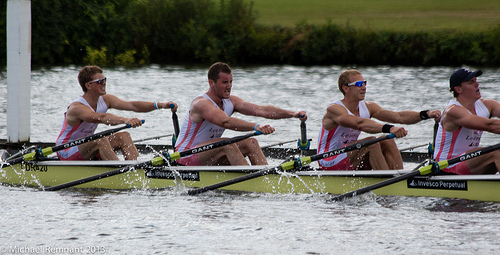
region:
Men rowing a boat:
[3, 61, 499, 198]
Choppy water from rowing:
[1, 165, 499, 243]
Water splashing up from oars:
[1, 160, 368, 197]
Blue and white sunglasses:
[346, 79, 369, 88]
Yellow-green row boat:
[3, 141, 499, 201]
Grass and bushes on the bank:
[32, 0, 499, 60]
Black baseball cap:
[451, 68, 483, 87]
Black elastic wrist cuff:
[418, 108, 431, 122]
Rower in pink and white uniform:
[56, 66, 177, 158]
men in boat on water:
[28, 51, 495, 208]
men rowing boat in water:
[31, 46, 475, 215]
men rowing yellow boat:
[25, 67, 499, 224]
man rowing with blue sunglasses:
[314, 53, 416, 190]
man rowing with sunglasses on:
[45, 44, 142, 171]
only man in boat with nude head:
[170, 55, 282, 195]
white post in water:
[3, 5, 49, 145]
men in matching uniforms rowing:
[21, 55, 496, 209]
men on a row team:
[37, 36, 496, 178]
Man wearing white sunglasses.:
[70, 62, 115, 94]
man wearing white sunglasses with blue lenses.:
[335, 63, 372, 111]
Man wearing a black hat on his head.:
[444, 57, 489, 104]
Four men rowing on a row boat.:
[5, 36, 497, 208]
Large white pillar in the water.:
[3, 2, 35, 146]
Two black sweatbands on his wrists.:
[375, 103, 445, 134]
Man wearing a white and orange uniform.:
[173, 57, 288, 167]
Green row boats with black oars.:
[7, 125, 498, 214]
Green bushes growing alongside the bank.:
[33, 4, 264, 66]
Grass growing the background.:
[260, 2, 496, 34]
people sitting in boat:
[65, 40, 492, 235]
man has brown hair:
[77, 61, 108, 99]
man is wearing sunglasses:
[87, 77, 118, 93]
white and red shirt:
[43, 95, 89, 155]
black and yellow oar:
[1, 101, 148, 196]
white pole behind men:
[0, 13, 32, 170]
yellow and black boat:
[26, 109, 498, 191]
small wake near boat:
[81, 133, 386, 224]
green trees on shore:
[13, 1, 265, 65]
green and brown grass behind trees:
[251, 1, 477, 46]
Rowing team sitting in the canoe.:
[15, 22, 498, 214]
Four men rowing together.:
[12, 37, 499, 197]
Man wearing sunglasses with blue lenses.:
[328, 68, 378, 98]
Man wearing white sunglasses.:
[75, 63, 116, 101]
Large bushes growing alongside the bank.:
[37, 2, 250, 61]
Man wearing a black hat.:
[440, 62, 488, 103]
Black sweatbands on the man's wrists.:
[379, 93, 439, 145]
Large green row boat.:
[5, 132, 497, 207]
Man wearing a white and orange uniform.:
[48, 57, 167, 168]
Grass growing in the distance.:
[265, 0, 498, 32]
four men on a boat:
[58, 63, 498, 178]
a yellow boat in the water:
[2, 155, 499, 204]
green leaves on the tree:
[193, 31, 206, 47]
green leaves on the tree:
[101, 34, 143, 69]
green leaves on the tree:
[139, 5, 161, 30]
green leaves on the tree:
[230, 9, 261, 43]